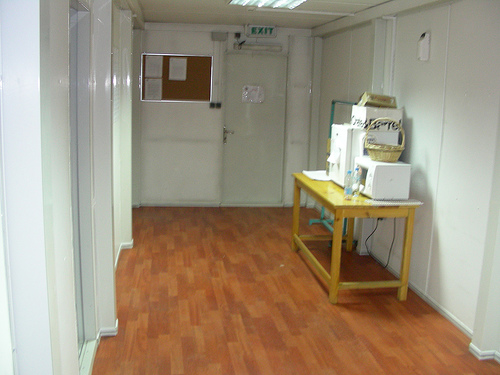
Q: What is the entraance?
A: Door.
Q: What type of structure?
A: Room.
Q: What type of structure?
A: Room.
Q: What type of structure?
A: Door.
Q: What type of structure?
A: Table.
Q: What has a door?
A: Wall.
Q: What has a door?
A: Wall.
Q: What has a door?
A: Wall.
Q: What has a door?
A: Wall.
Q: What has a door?
A: Wall.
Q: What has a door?
A: Wall.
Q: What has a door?
A: Wall.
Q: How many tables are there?
A: 1.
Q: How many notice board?
A: One.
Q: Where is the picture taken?
A: In the hallway.